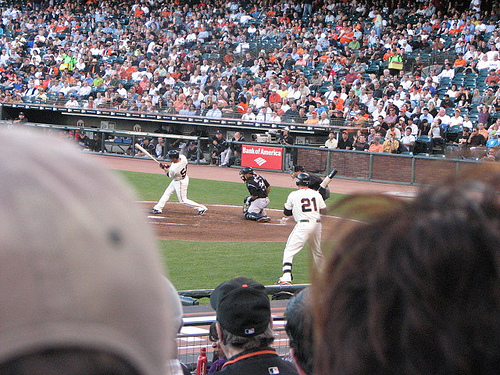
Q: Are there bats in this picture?
A: Yes, there is a bat.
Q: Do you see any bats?
A: Yes, there is a bat.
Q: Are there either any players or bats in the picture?
A: Yes, there is a bat.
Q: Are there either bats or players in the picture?
A: Yes, there is a bat.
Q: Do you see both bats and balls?
A: No, there is a bat but no balls.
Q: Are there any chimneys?
A: No, there are no chimneys.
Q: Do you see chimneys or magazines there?
A: No, there are no chimneys or magazines.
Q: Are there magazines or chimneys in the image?
A: No, there are no chimneys or magazines.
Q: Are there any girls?
A: No, there are no girls.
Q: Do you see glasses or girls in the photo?
A: No, there are no girls or glasses.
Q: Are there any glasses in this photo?
A: No, there are no glasses.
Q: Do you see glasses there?
A: No, there are no glasses.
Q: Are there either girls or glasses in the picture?
A: No, there are no glasses or girls.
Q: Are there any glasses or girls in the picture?
A: No, there are no glasses or girls.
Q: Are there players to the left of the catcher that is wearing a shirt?
A: Yes, there is a player to the left of the catcher.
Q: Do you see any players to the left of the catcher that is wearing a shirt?
A: Yes, there is a player to the left of the catcher.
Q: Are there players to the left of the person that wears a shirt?
A: Yes, there is a player to the left of the catcher.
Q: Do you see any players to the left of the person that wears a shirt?
A: Yes, there is a player to the left of the catcher.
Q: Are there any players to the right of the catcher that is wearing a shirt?
A: No, the player is to the left of the catcher.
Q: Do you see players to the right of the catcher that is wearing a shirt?
A: No, the player is to the left of the catcher.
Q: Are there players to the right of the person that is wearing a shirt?
A: No, the player is to the left of the catcher.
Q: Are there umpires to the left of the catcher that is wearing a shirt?
A: No, there is a player to the left of the catcher.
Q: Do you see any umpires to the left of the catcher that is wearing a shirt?
A: No, there is a player to the left of the catcher.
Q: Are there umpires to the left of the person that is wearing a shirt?
A: No, there is a player to the left of the catcher.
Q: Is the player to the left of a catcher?
A: Yes, the player is to the left of a catcher.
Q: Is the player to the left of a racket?
A: No, the player is to the left of a catcher.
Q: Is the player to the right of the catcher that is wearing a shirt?
A: No, the player is to the left of the catcher.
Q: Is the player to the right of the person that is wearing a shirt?
A: No, the player is to the left of the catcher.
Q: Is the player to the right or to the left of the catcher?
A: The player is to the left of the catcher.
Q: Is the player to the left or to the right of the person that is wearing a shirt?
A: The player is to the left of the catcher.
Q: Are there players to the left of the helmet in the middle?
A: Yes, there is a player to the left of the helmet.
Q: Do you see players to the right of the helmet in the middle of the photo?
A: No, the player is to the left of the helmet.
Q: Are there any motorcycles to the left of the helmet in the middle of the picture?
A: No, there is a player to the left of the helmet.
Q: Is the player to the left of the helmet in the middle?
A: Yes, the player is to the left of the helmet.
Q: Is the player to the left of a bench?
A: No, the player is to the left of the helmet.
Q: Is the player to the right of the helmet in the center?
A: No, the player is to the left of the helmet.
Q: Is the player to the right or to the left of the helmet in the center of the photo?
A: The player is to the left of the helmet.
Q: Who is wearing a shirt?
A: The catcher is wearing a shirt.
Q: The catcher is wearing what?
A: The catcher is wearing a shirt.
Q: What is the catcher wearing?
A: The catcher is wearing a shirt.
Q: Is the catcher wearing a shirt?
A: Yes, the catcher is wearing a shirt.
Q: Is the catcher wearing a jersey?
A: No, the catcher is wearing a shirt.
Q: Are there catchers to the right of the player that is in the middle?
A: Yes, there is a catcher to the right of the player.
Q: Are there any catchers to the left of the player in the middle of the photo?
A: No, the catcher is to the right of the player.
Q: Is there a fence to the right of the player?
A: No, there is a catcher to the right of the player.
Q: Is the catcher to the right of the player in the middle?
A: Yes, the catcher is to the right of the player.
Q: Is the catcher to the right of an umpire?
A: No, the catcher is to the right of the player.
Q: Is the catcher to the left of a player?
A: No, the catcher is to the right of a player.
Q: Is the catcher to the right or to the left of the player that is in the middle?
A: The catcher is to the right of the player.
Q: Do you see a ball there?
A: No, there are no balls.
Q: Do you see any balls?
A: No, there are no balls.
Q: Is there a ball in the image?
A: No, there are no balls.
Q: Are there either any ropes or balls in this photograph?
A: No, there are no balls or ropes.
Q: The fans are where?
A: The fans are in the bleachers.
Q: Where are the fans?
A: The fans are in the bleachers.